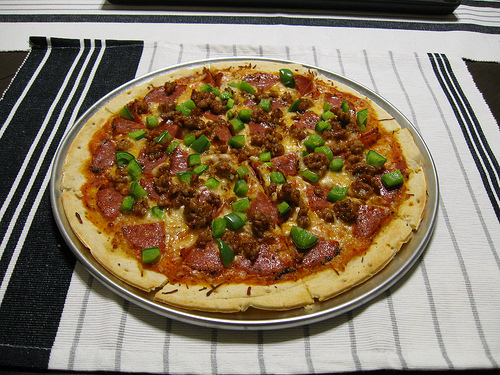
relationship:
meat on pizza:
[86, 68, 399, 277] [58, 58, 430, 315]